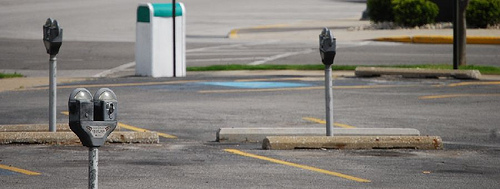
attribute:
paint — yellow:
[389, 28, 499, 52]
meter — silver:
[66, 80, 130, 187]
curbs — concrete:
[179, 122, 444, 151]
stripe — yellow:
[219, 143, 376, 187]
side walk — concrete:
[206, 11, 430, 63]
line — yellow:
[223, 144, 364, 183]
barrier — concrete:
[257, 132, 443, 154]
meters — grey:
[30, 16, 402, 181]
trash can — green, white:
[134, 0, 187, 79]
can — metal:
[132, 1, 187, 78]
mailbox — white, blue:
[129, 2, 184, 78]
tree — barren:
[428, 0, 487, 67]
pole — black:
[170, 1, 183, 82]